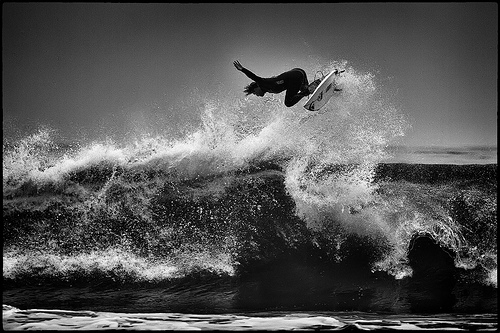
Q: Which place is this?
A: It is an ocean.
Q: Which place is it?
A: It is an ocean.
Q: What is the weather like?
A: It is clear.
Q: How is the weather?
A: It is clear.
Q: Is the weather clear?
A: Yes, it is clear.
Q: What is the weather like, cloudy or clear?
A: It is clear.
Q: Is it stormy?
A: No, it is clear.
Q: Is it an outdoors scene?
A: Yes, it is outdoors.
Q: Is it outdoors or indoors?
A: It is outdoors.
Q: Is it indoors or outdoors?
A: It is outdoors.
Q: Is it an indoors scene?
A: No, it is outdoors.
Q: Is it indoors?
A: No, it is outdoors.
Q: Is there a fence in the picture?
A: No, there are no fences.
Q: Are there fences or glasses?
A: No, there are no fences or glasses.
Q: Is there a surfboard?
A: Yes, there is a surfboard.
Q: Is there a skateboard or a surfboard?
A: Yes, there is a surfboard.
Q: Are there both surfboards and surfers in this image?
A: Yes, there are both a surfboard and a surfer.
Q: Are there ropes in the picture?
A: No, there are no ropes.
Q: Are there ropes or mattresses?
A: No, there are no ropes or mattresses.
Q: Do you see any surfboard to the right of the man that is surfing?
A: Yes, there is a surfboard to the right of the man.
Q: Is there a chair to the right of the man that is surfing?
A: No, there is a surfboard to the right of the man.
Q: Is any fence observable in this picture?
A: No, there are no fences.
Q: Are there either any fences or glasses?
A: No, there are no fences or glasses.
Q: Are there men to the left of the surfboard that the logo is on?
A: Yes, there is a man to the left of the surfboard.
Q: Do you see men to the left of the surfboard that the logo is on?
A: Yes, there is a man to the left of the surfboard.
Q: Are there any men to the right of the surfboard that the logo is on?
A: No, the man is to the left of the surfboard.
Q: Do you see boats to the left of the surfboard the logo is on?
A: No, there is a man to the left of the surf board.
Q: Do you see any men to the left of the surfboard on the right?
A: Yes, there is a man to the left of the surfboard.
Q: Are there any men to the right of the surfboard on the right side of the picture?
A: No, the man is to the left of the surfboard.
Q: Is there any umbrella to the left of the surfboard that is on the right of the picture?
A: No, there is a man to the left of the surfboard.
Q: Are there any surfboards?
A: Yes, there is a surfboard.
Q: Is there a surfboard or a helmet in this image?
A: Yes, there is a surfboard.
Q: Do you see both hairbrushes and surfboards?
A: No, there is a surfboard but no hairbrushes.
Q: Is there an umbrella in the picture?
A: No, there are no umbrellas.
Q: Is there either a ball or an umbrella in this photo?
A: No, there are no umbrellas or balls.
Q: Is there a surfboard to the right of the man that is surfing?
A: Yes, there is a surfboard to the right of the man.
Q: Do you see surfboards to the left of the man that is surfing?
A: No, the surfboard is to the right of the man.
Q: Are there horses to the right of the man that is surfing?
A: No, there is a surfboard to the right of the man.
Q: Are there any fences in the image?
A: No, there are no fences.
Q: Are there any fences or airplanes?
A: No, there are no fences or airplanes.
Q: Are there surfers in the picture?
A: Yes, there is a surfer.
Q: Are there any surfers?
A: Yes, there is a surfer.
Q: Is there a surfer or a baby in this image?
A: Yes, there is a surfer.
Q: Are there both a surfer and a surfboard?
A: Yes, there are both a surfer and a surfboard.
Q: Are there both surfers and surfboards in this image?
A: Yes, there are both a surfer and a surfboard.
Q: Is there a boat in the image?
A: No, there are no boats.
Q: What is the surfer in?
A: The surfer is in the air.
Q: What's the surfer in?
A: The surfer is in the air.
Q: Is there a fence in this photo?
A: No, there are no fences.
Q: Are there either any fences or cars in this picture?
A: No, there are no fences or cars.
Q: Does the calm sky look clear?
A: Yes, the sky is clear.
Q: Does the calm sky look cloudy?
A: No, the sky is clear.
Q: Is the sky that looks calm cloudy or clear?
A: The sky is clear.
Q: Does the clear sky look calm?
A: Yes, the sky is calm.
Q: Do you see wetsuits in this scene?
A: Yes, there is a wetsuit.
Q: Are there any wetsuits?
A: Yes, there is a wetsuit.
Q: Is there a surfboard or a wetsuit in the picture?
A: Yes, there is a wetsuit.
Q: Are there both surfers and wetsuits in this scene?
A: Yes, there are both a wetsuit and a surfer.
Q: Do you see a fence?
A: No, there are no fences.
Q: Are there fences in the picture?
A: No, there are no fences.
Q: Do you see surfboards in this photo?
A: Yes, there is a surfboard.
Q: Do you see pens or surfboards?
A: Yes, there is a surfboard.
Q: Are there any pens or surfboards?
A: Yes, there is a surfboard.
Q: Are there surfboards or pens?
A: Yes, there is a surfboard.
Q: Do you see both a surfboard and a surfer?
A: Yes, there are both a surfboard and a surfer.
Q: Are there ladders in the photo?
A: No, there are no ladders.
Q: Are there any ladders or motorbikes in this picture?
A: No, there are no ladders or motorbikes.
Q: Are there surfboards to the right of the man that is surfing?
A: Yes, there is a surfboard to the right of the man.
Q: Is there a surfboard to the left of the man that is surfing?
A: No, the surfboard is to the right of the man.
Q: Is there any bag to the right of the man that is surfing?
A: No, there is a surfboard to the right of the man.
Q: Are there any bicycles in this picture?
A: No, there are no bicycles.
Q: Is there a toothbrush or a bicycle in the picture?
A: No, there are no bicycles or toothbrushes.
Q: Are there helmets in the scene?
A: No, there are no helmets.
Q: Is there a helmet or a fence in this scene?
A: No, there are no helmets or fences.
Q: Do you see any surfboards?
A: Yes, there is a surfboard.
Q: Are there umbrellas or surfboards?
A: Yes, there is a surfboard.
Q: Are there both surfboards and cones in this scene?
A: No, there is a surfboard but no cones.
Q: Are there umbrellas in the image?
A: No, there are no umbrellas.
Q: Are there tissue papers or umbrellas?
A: No, there are no umbrellas or tissue papers.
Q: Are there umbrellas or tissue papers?
A: No, there are no umbrellas or tissue papers.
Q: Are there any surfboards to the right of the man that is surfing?
A: Yes, there is a surfboard to the right of the man.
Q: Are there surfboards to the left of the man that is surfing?
A: No, the surfboard is to the right of the man.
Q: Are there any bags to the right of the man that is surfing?
A: No, there is a surfboard to the right of the man.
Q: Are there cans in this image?
A: No, there are no cans.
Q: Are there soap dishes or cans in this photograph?
A: No, there are no cans or soap dishes.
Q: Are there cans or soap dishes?
A: No, there are no cans or soap dishes.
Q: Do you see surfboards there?
A: Yes, there is a surfboard.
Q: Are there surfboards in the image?
A: Yes, there is a surfboard.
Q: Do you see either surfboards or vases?
A: Yes, there is a surfboard.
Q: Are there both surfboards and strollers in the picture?
A: No, there is a surfboard but no strollers.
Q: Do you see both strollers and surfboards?
A: No, there is a surfboard but no strollers.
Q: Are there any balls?
A: No, there are no balls.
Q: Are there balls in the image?
A: No, there are no balls.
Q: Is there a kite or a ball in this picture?
A: No, there are no balls or kites.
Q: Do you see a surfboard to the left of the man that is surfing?
A: No, the surfboard is to the right of the man.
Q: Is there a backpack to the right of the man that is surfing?
A: No, there is a surfboard to the right of the man.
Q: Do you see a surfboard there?
A: Yes, there is a surfboard.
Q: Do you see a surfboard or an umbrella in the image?
A: Yes, there is a surfboard.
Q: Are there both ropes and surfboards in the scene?
A: No, there is a surfboard but no ropes.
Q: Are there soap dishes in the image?
A: No, there are no soap dishes.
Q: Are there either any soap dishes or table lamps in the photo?
A: No, there are no soap dishes or table lamps.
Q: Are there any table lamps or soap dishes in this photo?
A: No, there are no soap dishes or table lamps.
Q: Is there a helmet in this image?
A: No, there are no helmets.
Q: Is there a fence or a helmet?
A: No, there are no helmets or fences.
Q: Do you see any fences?
A: No, there are no fences.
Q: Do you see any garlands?
A: No, there are no garlands.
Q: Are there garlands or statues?
A: No, there are no garlands or statues.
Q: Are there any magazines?
A: No, there are no magazines.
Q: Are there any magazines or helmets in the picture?
A: No, there are no magazines or helmets.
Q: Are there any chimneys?
A: No, there are no chimneys.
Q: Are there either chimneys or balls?
A: No, there are no chimneys or balls.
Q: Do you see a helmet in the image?
A: No, there are no helmets.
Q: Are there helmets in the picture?
A: No, there are no helmets.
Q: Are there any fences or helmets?
A: No, there are no helmets or fences.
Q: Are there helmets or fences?
A: No, there are no helmets or fences.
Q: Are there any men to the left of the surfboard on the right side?
A: Yes, there is a man to the left of the surfboard.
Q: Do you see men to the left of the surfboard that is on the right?
A: Yes, there is a man to the left of the surfboard.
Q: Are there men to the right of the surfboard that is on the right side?
A: No, the man is to the left of the surfboard.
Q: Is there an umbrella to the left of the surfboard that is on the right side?
A: No, there is a man to the left of the surfboard.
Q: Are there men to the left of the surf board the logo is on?
A: Yes, there is a man to the left of the surfboard.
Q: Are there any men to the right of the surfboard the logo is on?
A: No, the man is to the left of the surfboard.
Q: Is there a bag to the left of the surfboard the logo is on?
A: No, there is a man to the left of the surfboard.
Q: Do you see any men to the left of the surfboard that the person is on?
A: Yes, there is a man to the left of the surfboard.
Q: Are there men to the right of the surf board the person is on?
A: No, the man is to the left of the surfboard.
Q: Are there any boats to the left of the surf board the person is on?
A: No, there is a man to the left of the surfboard.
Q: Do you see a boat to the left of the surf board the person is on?
A: No, there is a man to the left of the surfboard.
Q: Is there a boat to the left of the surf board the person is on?
A: No, there is a man to the left of the surfboard.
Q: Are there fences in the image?
A: No, there are no fences.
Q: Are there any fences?
A: No, there are no fences.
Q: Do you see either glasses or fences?
A: No, there are no fences or glasses.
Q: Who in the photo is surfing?
A: The man is surfing.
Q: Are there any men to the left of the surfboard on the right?
A: Yes, there is a man to the left of the surfboard.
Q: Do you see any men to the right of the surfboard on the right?
A: No, the man is to the left of the surfboard.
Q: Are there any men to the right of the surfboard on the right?
A: No, the man is to the left of the surfboard.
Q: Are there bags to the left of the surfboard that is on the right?
A: No, there is a man to the left of the surfboard.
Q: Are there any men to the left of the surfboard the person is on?
A: Yes, there is a man to the left of the surfboard.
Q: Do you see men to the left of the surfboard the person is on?
A: Yes, there is a man to the left of the surfboard.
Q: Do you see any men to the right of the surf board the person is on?
A: No, the man is to the left of the surfboard.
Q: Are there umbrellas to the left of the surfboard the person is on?
A: No, there is a man to the left of the surfboard.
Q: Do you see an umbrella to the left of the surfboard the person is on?
A: No, there is a man to the left of the surfboard.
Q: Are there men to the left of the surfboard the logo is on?
A: Yes, there is a man to the left of the surfboard.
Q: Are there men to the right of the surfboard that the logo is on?
A: No, the man is to the left of the surfboard.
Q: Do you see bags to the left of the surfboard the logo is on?
A: No, there is a man to the left of the surfboard.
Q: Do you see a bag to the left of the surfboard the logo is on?
A: No, there is a man to the left of the surfboard.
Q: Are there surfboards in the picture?
A: Yes, there is a surfboard.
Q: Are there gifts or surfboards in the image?
A: Yes, there is a surfboard.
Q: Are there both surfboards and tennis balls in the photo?
A: No, there is a surfboard but no tennis balls.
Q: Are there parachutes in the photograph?
A: No, there are no parachutes.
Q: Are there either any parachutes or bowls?
A: No, there are no parachutes or bowls.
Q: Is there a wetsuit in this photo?
A: Yes, there is a wetsuit.